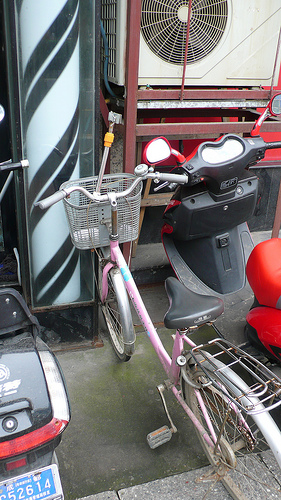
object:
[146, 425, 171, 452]
pedal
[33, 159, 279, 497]
bicycle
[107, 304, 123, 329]
spokes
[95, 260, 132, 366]
wheel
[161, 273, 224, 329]
seat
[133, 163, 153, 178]
bell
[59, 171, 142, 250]
basket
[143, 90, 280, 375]
scooter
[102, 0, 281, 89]
air conditioner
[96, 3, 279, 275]
stand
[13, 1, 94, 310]
pole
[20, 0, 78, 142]
ribbon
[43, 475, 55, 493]
number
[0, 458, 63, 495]
plate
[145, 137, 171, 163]
mirror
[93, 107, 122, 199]
pipe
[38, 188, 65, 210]
handlebars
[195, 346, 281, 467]
fender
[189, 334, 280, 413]
rack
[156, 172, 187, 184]
handle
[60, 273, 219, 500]
floor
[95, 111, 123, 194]
tube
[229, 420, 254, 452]
chain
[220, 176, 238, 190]
logo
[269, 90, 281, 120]
mirror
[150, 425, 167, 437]
reflector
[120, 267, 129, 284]
logo